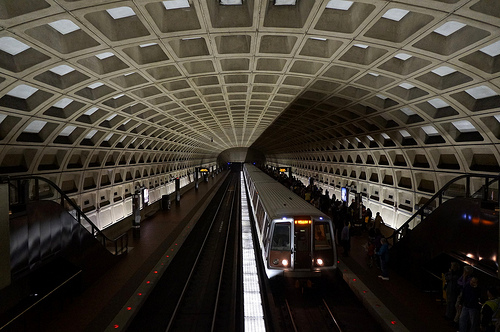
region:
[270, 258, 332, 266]
Lights on the front of the subway train.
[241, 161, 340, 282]
A subway train.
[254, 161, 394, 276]
People waiting on the subway train.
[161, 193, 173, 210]
A trash receptacle.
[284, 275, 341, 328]
Subway train rails.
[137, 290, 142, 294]
A small red warning light.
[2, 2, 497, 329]
A busy underground subway tunnel.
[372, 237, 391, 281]
A person wearing white shoes waiting on the platform.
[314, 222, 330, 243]
Driver of the subway train.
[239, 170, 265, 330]
Lights separating the subway train tracks.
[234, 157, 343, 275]
train in train station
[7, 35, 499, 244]
tunnel that train is in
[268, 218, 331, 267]
front window of train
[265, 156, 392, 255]
people waiting on train platform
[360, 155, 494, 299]
flight of stairs on right side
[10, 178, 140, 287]
flight of stairs on left side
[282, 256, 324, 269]
front lights of train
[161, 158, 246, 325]
unused train tracks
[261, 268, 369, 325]
tracks train is on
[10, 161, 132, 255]
railing of staircase on left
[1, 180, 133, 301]
escalator to the left of the train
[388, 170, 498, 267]
escalator to the right of the train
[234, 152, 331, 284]
a metal subway train loading passengers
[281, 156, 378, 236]
many people unloading from the train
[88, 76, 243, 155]
white concrete and glass cieling of the subway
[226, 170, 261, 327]
lighted concrete divider of the train tracks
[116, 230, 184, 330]
red lights on the edge of the subway dock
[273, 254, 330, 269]
lights on the front of the train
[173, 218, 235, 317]
empty set of train tracks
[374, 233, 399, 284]
a person wearing a blue shirt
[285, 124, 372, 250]
people at the platform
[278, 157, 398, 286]
people at the platform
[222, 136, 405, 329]
the train in the train station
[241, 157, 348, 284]
train arriving to station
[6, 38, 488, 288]
tunnel train is coming thru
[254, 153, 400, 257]
people waiting for train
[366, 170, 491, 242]
rail of staircase on right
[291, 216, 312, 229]
lit up sign on front of train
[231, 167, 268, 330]
divider between train tracks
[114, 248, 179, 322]
red reflectors beside train track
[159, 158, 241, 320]
train tracks not being used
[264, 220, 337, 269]
windshield of train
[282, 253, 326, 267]
headlights of the train